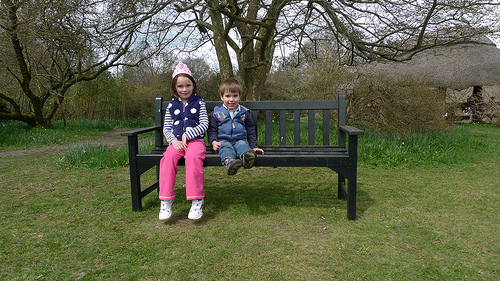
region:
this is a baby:
[213, 54, 250, 175]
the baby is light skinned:
[223, 96, 240, 103]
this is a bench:
[268, 89, 349, 204]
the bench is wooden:
[287, 96, 351, 134]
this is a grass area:
[378, 167, 490, 276]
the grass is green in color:
[398, 165, 454, 234]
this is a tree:
[48, 11, 137, 102]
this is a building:
[445, 40, 490, 117]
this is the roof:
[434, 52, 469, 75]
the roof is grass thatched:
[447, 51, 498, 76]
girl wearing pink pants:
[163, 140, 203, 190]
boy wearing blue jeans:
[219, 138, 265, 153]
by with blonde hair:
[218, 80, 244, 105]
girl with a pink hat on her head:
[165, 53, 196, 85]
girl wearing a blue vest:
[159, 99, 209, 141]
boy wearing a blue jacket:
[210, 107, 244, 134]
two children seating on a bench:
[156, 54, 259, 231]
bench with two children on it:
[155, 63, 267, 230]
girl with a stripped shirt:
[167, 98, 209, 145]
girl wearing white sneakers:
[153, 193, 210, 224]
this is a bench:
[280, 90, 357, 175]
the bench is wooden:
[268, 94, 343, 174]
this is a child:
[211, 75, 259, 161]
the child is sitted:
[210, 75, 262, 160]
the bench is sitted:
[257, 91, 353, 189]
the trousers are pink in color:
[158, 143, 206, 200]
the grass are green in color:
[235, 192, 324, 274]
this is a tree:
[203, 0, 334, 65]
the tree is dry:
[266, 13, 366, 60]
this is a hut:
[447, 45, 494, 71]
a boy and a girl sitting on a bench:
[123, 60, 365, 222]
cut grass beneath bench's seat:
[7, 146, 499, 279]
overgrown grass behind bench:
[51, 97, 482, 218]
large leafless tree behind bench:
[122, 0, 498, 222]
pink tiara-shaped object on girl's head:
[168, 60, 195, 99]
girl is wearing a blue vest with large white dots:
[169, 96, 200, 141]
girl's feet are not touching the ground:
[156, 194, 205, 228]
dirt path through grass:
[3, 128, 139, 184]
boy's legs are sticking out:
[217, 138, 259, 175]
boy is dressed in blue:
[208, 79, 258, 171]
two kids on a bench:
[124, 57, 281, 232]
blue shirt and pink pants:
[140, 93, 223, 214]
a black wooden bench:
[115, 72, 433, 259]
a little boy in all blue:
[201, 76, 271, 183]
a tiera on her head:
[169, 54, 204, 84]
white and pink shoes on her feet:
[146, 198, 226, 228]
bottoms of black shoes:
[233, 145, 263, 185]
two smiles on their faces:
[175, 80, 262, 115]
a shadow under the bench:
[155, 169, 402, 229]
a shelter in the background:
[330, 20, 498, 125]